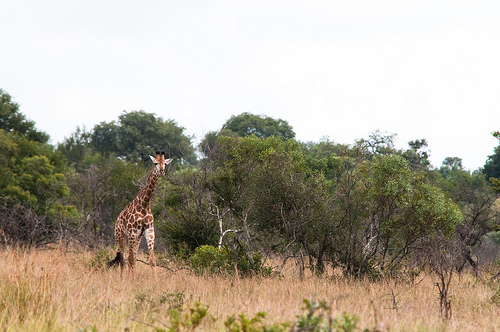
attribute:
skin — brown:
[129, 222, 144, 230]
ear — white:
[144, 152, 160, 161]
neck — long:
[134, 185, 166, 205]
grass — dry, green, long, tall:
[197, 266, 229, 278]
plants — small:
[17, 277, 111, 316]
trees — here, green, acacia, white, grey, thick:
[249, 140, 354, 200]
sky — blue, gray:
[259, 17, 285, 34]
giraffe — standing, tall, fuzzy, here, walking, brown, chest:
[128, 145, 180, 276]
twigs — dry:
[355, 274, 400, 293]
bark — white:
[209, 237, 237, 253]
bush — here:
[165, 238, 235, 286]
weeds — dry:
[84, 294, 122, 315]